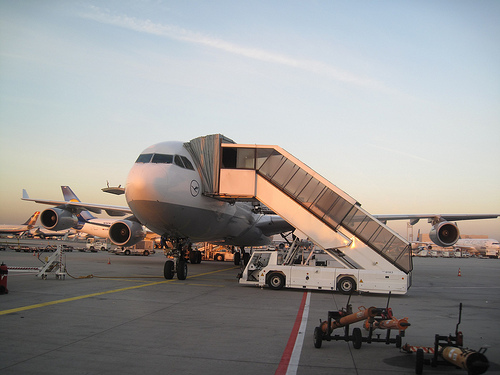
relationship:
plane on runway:
[16, 124, 498, 304] [1, 249, 499, 371]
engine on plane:
[108, 224, 130, 243] [119, 140, 280, 270]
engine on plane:
[432, 222, 456, 244] [119, 140, 280, 270]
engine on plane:
[40, 210, 57, 230] [119, 140, 280, 270]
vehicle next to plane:
[240, 222, 417, 295] [21, 139, 498, 284]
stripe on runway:
[250, 291, 370, 351] [1, 249, 499, 371]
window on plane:
[134, 149, 194, 172] [21, 139, 498, 284]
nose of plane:
[127, 165, 158, 199] [64, 112, 336, 267]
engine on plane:
[429, 221, 460, 247] [71, 125, 491, 292]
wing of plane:
[33, 184, 122, 251] [17, 133, 413, 293]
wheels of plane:
[164, 252, 187, 281] [21, 139, 498, 284]